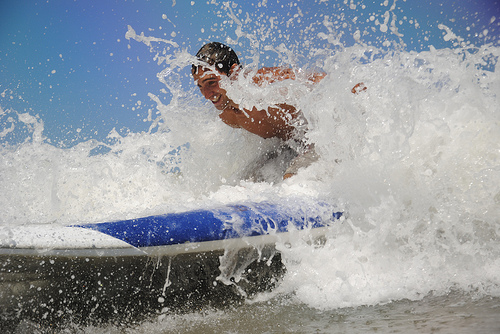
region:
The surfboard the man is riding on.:
[1, 197, 347, 255]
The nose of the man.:
[202, 89, 210, 99]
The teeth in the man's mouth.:
[212, 97, 218, 102]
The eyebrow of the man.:
[200, 73, 217, 85]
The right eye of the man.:
[210, 79, 216, 85]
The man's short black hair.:
[190, 42, 235, 75]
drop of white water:
[107, 49, 116, 59]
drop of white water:
[126, 41, 133, 49]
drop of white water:
[116, 35, 122, 42]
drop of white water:
[91, 38, 98, 47]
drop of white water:
[56, 51, 63, 58]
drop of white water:
[49, 67, 59, 76]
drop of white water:
[45, 83, 55, 91]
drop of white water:
[72, 125, 84, 133]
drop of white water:
[412, 20, 422, 28]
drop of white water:
[358, 3, 367, 10]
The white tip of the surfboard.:
[2, 223, 128, 264]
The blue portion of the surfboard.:
[115, 196, 353, 247]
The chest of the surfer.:
[239, 108, 301, 142]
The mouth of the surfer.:
[210, 94, 223, 106]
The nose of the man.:
[202, 87, 214, 97]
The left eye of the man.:
[196, 82, 204, 90]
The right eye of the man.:
[206, 79, 217, 86]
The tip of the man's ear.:
[227, 60, 240, 74]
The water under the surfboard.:
[5, 282, 498, 329]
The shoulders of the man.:
[217, 71, 318, 132]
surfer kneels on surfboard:
[187, 40, 363, 191]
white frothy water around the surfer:
[235, 12, 496, 302]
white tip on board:
[5, 226, 125, 246]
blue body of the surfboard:
[85, 195, 306, 236]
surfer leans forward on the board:
[180, 30, 355, 200]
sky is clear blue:
[1, 0, 496, 132]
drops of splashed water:
[0, 255, 283, 330]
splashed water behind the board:
[2, 85, 217, 220]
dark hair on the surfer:
[190, 38, 236, 73]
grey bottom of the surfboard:
[6, 241, 331, 258]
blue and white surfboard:
[6, 183, 363, 273]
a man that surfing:
[177, 36, 404, 165]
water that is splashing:
[4, 69, 498, 246]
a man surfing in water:
[0, 34, 417, 256]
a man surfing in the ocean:
[1, 39, 373, 266]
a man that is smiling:
[186, 40, 353, 157]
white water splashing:
[305, 59, 490, 263]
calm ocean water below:
[86, 283, 493, 322]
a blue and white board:
[4, 200, 327, 247]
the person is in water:
[178, 29, 355, 180]